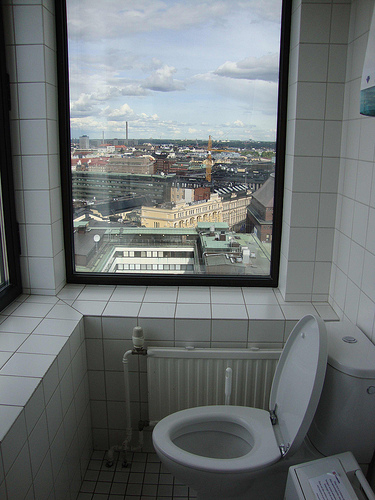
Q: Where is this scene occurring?
A: A bathroom.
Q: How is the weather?
A: Cool and overcast.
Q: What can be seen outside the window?
A: A big city.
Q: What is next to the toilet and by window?
A: A radiator.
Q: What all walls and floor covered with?
A: Tile.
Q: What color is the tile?
A: White.